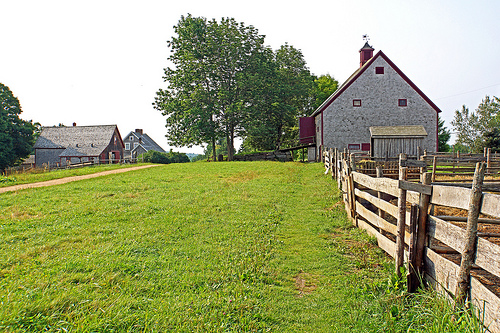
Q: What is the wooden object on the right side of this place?
A: A fence.